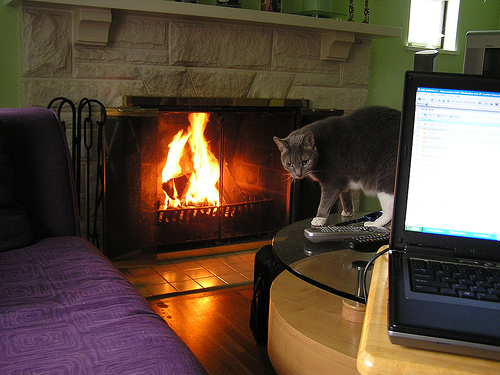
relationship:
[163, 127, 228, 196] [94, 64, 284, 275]
fire in fireplace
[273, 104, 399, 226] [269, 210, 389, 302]
cat on table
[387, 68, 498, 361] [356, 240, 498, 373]
laptop on tv table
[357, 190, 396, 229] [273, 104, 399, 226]
leg of cat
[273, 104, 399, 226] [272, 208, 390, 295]
cat standing on top of coffee table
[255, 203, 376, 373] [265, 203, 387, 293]
coffee table has a top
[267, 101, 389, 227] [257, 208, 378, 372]
cat standing on a table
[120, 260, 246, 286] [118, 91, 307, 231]
tile in front of fireplace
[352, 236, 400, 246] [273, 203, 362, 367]
remote on table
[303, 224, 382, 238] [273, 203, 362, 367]
remote control on table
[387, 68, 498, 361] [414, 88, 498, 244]
laptop has a screen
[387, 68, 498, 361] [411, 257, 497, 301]
laptop has a keyboard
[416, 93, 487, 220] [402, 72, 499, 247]
browser window on screen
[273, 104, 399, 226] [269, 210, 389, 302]
cat standing on table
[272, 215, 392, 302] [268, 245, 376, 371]
table top on a base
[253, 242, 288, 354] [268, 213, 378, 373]
suitcase behind a table